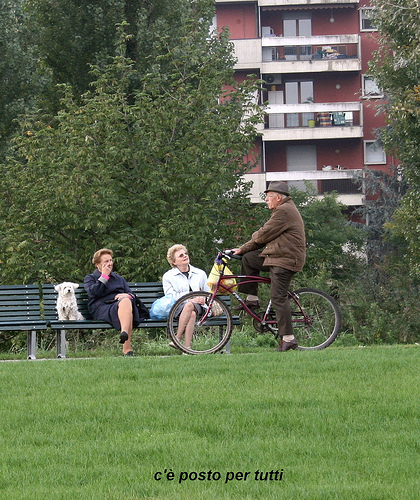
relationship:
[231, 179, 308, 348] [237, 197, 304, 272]
man wearing jacket